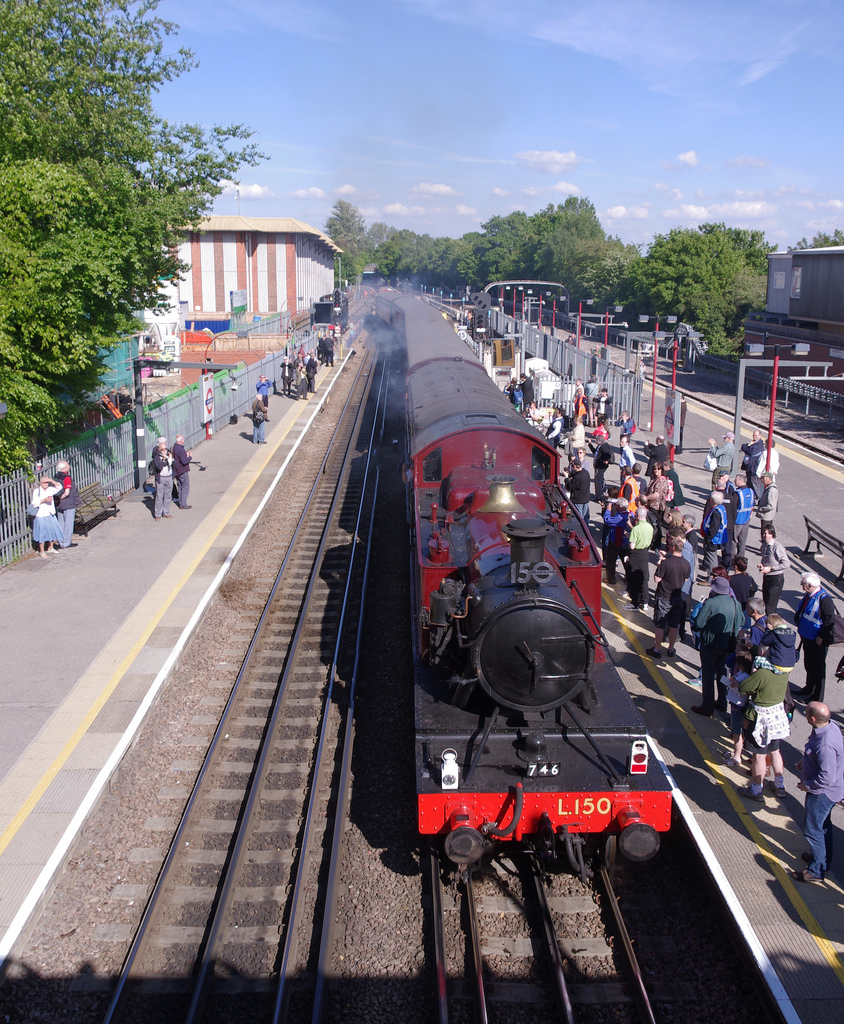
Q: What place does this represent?
A: It represents the station.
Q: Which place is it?
A: It is a station.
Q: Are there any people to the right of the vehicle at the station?
A: Yes, there is a person to the right of the train.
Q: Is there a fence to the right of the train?
A: No, there is a person to the right of the train.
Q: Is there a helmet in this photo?
A: No, there are no helmets.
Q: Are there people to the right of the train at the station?
A: Yes, there is a person to the right of the train.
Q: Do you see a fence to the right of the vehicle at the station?
A: No, there is a person to the right of the train.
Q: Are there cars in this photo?
A: No, there are no cars.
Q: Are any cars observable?
A: No, there are no cars.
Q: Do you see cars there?
A: No, there are no cars.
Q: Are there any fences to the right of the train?
A: No, there is a person to the right of the train.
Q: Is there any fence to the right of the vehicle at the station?
A: No, there is a person to the right of the train.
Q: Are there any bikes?
A: No, there are no bikes.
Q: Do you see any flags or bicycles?
A: No, there are no bicycles or flags.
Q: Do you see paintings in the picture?
A: No, there are no paintings.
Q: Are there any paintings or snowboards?
A: No, there are no paintings or snowboards.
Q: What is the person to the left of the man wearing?
A: The person is wearing a shirt.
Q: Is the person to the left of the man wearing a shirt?
A: Yes, the person is wearing a shirt.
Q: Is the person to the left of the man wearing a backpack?
A: No, the person is wearing a shirt.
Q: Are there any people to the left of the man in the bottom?
A: Yes, there is a person to the left of the man.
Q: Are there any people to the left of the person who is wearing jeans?
A: Yes, there is a person to the left of the man.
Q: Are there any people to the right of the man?
A: No, the person is to the left of the man.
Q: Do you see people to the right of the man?
A: No, the person is to the left of the man.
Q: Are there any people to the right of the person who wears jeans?
A: No, the person is to the left of the man.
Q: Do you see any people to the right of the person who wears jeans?
A: No, the person is to the left of the man.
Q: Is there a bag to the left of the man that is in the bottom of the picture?
A: No, there is a person to the left of the man.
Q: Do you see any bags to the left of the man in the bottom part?
A: No, there is a person to the left of the man.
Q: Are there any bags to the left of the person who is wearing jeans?
A: No, there is a person to the left of the man.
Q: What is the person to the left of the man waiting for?
A: The person is waiting for the train.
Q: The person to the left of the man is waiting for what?
A: The person is waiting for the train.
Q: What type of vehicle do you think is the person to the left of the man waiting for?
A: The person is waiting for the train.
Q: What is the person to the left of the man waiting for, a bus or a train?
A: The person is waiting for a train.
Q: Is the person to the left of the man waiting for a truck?
A: No, the person is waiting for the train.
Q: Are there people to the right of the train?
A: Yes, there is a person to the right of the train.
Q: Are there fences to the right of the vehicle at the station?
A: No, there is a person to the right of the train.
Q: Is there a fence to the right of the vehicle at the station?
A: No, there is a person to the right of the train.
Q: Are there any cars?
A: No, there are no cars.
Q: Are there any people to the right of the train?
A: Yes, there are people to the right of the train.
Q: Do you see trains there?
A: Yes, there is a train.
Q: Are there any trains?
A: Yes, there is a train.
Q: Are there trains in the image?
A: Yes, there is a train.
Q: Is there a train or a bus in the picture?
A: Yes, there is a train.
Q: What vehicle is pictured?
A: The vehicle is a train.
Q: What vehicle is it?
A: The vehicle is a train.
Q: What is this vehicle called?
A: This is a train.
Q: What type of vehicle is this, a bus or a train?
A: This is a train.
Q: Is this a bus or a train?
A: This is a train.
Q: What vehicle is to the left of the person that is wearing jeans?
A: The vehicle is a train.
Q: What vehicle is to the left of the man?
A: The vehicle is a train.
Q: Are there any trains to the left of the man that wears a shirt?
A: Yes, there is a train to the left of the man.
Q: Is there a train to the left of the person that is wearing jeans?
A: Yes, there is a train to the left of the man.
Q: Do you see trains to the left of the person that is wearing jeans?
A: Yes, there is a train to the left of the man.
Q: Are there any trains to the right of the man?
A: No, the train is to the left of the man.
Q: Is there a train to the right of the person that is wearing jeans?
A: No, the train is to the left of the man.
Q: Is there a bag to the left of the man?
A: No, there is a train to the left of the man.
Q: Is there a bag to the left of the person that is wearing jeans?
A: No, there is a train to the left of the man.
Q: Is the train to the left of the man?
A: Yes, the train is to the left of the man.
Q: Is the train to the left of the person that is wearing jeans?
A: Yes, the train is to the left of the man.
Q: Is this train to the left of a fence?
A: No, the train is to the left of the man.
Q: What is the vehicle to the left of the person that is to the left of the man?
A: The vehicle is a train.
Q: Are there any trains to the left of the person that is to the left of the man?
A: Yes, there is a train to the left of the person.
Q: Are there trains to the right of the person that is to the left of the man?
A: No, the train is to the left of the person.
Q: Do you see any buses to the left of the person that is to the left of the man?
A: No, there is a train to the left of the person.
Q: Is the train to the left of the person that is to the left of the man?
A: Yes, the train is to the left of the person.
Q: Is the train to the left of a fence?
A: No, the train is to the left of the person.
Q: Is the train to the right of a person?
A: No, the train is to the left of a person.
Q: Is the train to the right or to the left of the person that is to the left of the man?
A: The train is to the left of the person.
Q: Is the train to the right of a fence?
A: No, the train is to the right of a person.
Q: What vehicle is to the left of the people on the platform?
A: The vehicle is a train.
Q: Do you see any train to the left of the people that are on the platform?
A: Yes, there is a train to the left of the people.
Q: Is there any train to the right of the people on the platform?
A: No, the train is to the left of the people.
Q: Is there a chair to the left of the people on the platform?
A: No, there is a train to the left of the people.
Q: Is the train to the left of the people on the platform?
A: Yes, the train is to the left of the people.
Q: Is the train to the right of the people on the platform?
A: No, the train is to the left of the people.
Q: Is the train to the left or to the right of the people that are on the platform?
A: The train is to the left of the people.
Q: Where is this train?
A: The train is at the station.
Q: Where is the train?
A: The train is at the station.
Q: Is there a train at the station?
A: Yes, there is a train at the station.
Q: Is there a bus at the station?
A: No, there is a train at the station.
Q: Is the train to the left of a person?
A: No, the train is to the right of a person.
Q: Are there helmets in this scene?
A: No, there are no helmets.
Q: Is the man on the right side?
A: Yes, the man is on the right of the image.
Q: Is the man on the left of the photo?
A: No, the man is on the right of the image.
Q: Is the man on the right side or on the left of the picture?
A: The man is on the right of the image.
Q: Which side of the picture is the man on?
A: The man is on the right of the image.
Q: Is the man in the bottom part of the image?
A: Yes, the man is in the bottom of the image.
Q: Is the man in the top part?
A: No, the man is in the bottom of the image.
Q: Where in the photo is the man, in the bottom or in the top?
A: The man is in the bottom of the image.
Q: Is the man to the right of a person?
A: Yes, the man is to the right of a person.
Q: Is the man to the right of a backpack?
A: No, the man is to the right of a person.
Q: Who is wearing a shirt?
A: The man is wearing a shirt.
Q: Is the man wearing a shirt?
A: Yes, the man is wearing a shirt.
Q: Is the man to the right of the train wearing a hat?
A: No, the man is wearing a shirt.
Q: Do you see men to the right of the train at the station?
A: Yes, there is a man to the right of the train.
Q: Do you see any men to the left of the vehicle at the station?
A: No, the man is to the right of the train.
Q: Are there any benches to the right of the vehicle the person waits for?
A: No, there is a man to the right of the train.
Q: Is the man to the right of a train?
A: Yes, the man is to the right of a train.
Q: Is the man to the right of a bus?
A: No, the man is to the right of a train.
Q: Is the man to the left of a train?
A: No, the man is to the right of a train.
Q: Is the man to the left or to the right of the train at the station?
A: The man is to the right of the train.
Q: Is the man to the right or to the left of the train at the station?
A: The man is to the right of the train.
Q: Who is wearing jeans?
A: The man is wearing jeans.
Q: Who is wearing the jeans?
A: The man is wearing jeans.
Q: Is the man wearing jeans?
A: Yes, the man is wearing jeans.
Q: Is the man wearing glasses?
A: No, the man is wearing jeans.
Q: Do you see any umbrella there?
A: No, there are no umbrellas.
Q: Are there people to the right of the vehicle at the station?
A: Yes, there are people to the right of the train.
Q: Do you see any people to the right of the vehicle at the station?
A: Yes, there are people to the right of the train.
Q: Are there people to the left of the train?
A: No, the people are to the right of the train.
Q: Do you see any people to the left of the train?
A: No, the people are to the right of the train.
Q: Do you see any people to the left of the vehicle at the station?
A: No, the people are to the right of the train.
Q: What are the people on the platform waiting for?
A: The people are waiting for the train.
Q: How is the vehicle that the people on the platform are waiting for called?
A: The vehicle is a train.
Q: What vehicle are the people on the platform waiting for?
A: The people are waiting for the train.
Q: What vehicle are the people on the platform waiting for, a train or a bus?
A: The people are waiting for a train.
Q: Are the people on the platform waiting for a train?
A: Yes, the people are waiting for a train.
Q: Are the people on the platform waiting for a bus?
A: No, the people are waiting for a train.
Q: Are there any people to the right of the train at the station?
A: Yes, there is a person to the right of the train.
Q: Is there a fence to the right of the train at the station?
A: No, there is a person to the right of the train.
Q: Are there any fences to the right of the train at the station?
A: No, there is a person to the right of the train.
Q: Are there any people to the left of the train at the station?
A: Yes, there is a person to the left of the train.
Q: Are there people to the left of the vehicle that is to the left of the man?
A: Yes, there is a person to the left of the train.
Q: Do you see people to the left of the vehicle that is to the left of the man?
A: Yes, there is a person to the left of the train.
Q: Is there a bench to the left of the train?
A: No, there is a person to the left of the train.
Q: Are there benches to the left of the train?
A: No, there is a person to the left of the train.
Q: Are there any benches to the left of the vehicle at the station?
A: No, there is a person to the left of the train.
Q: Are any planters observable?
A: No, there are no planters.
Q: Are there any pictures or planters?
A: No, there are no planters or pictures.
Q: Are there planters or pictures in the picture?
A: No, there are no planters or pictures.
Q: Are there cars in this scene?
A: No, there are no cars.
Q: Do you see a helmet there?
A: No, there are no helmets.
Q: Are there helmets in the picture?
A: No, there are no helmets.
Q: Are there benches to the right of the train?
A: No, there is a person to the right of the train.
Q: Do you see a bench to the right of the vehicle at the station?
A: No, there is a person to the right of the train.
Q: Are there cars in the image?
A: No, there are no cars.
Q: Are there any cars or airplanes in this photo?
A: No, there are no cars or airplanes.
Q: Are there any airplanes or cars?
A: No, there are no cars or airplanes.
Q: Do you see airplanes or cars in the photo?
A: No, there are no cars or airplanes.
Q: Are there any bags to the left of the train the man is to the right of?
A: No, there is a person to the left of the train.